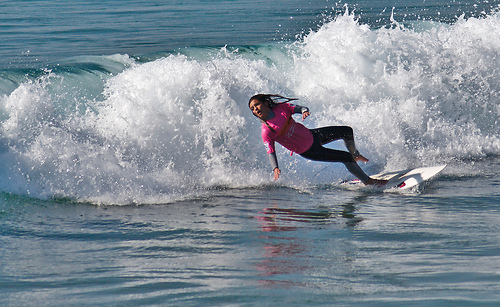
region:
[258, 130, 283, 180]
the arm of a woman surfing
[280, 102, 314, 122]
the arm of a woman surfing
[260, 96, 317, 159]
a woman with a pink shirt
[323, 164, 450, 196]
a white surf board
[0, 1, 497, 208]
a large wave behind a surfer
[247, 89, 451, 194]
a woman with her foot on a surf board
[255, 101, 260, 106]
the left eye of a woman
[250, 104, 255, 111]
the right eye of a woman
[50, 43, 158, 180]
the water is stirred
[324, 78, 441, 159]
the water is stirred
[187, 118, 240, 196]
the water is stirred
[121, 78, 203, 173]
the water is stirred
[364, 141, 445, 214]
this is a surf board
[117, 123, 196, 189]
the water is stirred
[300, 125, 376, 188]
woman wearing black pants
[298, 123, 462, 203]
woman on a white surfboard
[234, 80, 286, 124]
woman with black hair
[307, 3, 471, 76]
water spraying in the air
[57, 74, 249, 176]
waves crashing in the ocean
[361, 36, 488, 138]
waves crashing in the ocean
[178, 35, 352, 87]
waves crashing in the ocean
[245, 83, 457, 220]
woman falling of the surfboard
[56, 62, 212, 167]
waves in the ocean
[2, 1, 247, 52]
large body of water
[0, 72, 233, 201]
white waves in the water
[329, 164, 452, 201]
white surfboard in water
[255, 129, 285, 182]
the woman's right arm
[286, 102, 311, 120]
the woman's left arm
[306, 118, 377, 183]
black pants on the woman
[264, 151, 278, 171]
gray band on woman's arm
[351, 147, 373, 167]
the woman's left leg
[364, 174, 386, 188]
the woman's right foot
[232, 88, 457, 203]
a women surfing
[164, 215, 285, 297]
the water is blue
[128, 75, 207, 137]
the water is white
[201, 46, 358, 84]
a wave in the water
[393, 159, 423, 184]
a shadow on the surfboard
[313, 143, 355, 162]
black pants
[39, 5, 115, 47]
the water is blue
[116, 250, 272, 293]
the blue water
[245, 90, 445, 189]
woman falling off a surfboard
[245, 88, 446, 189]
woman wearing pink shirt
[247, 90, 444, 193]
woman surfing in the ocean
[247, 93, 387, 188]
woman wearing black pants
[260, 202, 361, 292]
reflection of woman on the water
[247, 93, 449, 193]
woman falling off white surfboard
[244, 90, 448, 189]
woman sideways on white surfboard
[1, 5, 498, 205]
large wave in the ocean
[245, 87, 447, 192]
woman falling from surfboard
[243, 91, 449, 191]
woman in pink shirt falling off surfboard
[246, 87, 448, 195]
woman with long black hair surfing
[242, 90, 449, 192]
woman with long black hair on surfboard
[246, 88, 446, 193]
woman on surfboard with left leg in air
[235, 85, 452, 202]
woman standing on surfboard with right leg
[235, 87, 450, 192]
woman standing on surfboard with one leg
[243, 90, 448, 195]
woman on surfboard with mouth open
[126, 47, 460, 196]
white wave behind woman surfer